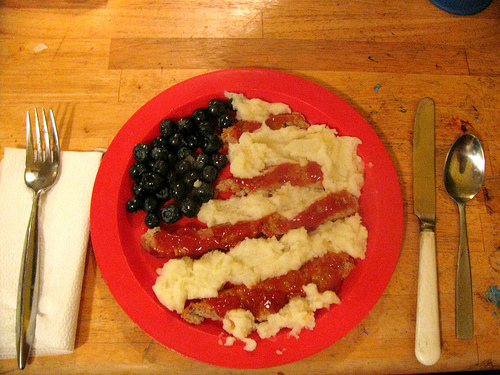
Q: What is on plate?
A: Food.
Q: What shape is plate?
A: Round.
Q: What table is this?
A: Wood.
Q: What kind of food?
A: Berries.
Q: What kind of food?
A: Bacon.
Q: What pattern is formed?
A: Stripes.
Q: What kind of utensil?
A: Knife.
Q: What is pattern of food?
A: American flag.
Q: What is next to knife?
A: Spoon.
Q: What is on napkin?
A: Fork.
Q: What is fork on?
A: Napkin.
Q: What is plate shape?
A: Round.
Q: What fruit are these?
A: Blueberries.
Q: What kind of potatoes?
A: Mashed.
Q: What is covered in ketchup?
A: Chicken.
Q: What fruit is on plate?
A: Blueberries.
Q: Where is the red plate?
A: On the table.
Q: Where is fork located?
A: Left of plate.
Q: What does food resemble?
A: Flag.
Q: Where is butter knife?
A: By spoon.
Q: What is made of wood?
A: Table.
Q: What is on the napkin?
A: Fork.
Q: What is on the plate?
A: Blueberries, mashed potatoes.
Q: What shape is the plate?
A: Round.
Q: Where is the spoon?
A: Next to the knife.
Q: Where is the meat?
A: Under the ketchup.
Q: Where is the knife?
A: Next to the spoon.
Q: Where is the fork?
A: On the left side of the plate.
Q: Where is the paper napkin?
A: Under the fork.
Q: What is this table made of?
A: Wood.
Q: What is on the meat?
A: Ketchup.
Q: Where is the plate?
A: On the table.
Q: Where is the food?
A: On the red plate.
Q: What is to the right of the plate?
A: A knife and spoon.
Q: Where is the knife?
A: Between the spoon and plate.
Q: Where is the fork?
A: To the left of the plate.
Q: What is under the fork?
A: A napkin.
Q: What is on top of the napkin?
A: A fork.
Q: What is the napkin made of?
A: Paper.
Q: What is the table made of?
A: Wood.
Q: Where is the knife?
A: On the right side of the plate.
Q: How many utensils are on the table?
A: 3.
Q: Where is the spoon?
A: On the right side of the knife.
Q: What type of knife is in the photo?
A: Butter knife.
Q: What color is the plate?
A: Red.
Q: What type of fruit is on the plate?
A: Berries.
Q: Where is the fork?
A: On the left side of the plate.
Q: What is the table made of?
A: Wood.